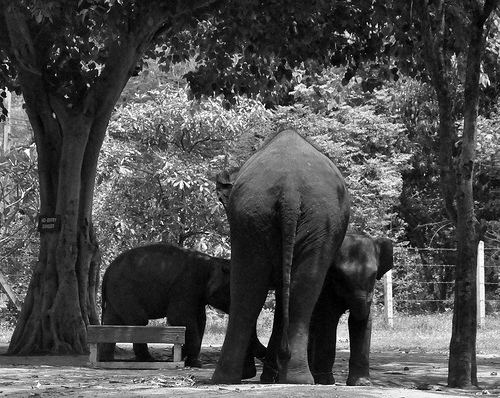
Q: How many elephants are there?
A: 3.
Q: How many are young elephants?
A: 2.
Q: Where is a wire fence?
A: Behind the elephants.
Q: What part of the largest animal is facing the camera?
A: The tail.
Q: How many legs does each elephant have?
A: 4.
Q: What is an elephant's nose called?
A: A trunk.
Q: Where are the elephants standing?
A: Under the trees.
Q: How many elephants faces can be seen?
A: 1.